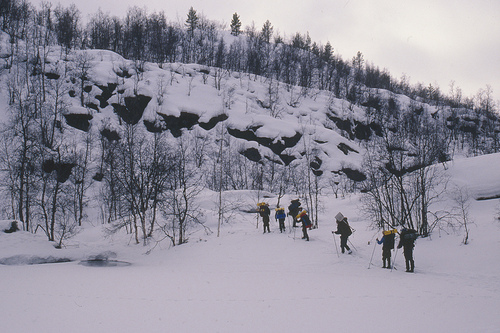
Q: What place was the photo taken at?
A: It was taken at the place.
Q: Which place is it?
A: It is a place.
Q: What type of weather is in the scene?
A: It is cloudy.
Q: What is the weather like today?
A: It is cloudy.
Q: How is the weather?
A: It is cloudy.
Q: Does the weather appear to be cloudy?
A: Yes, it is cloudy.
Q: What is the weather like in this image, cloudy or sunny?
A: It is cloudy.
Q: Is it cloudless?
A: No, it is cloudy.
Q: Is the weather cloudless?
A: No, it is cloudy.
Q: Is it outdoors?
A: Yes, it is outdoors.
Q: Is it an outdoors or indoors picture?
A: It is outdoors.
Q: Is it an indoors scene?
A: No, it is outdoors.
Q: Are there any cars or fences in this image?
A: No, there are no fences or cars.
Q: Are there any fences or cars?
A: No, there are no fences or cars.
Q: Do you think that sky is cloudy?
A: Yes, the sky is cloudy.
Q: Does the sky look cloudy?
A: Yes, the sky is cloudy.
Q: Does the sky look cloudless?
A: No, the sky is cloudy.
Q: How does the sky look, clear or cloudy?
A: The sky is cloudy.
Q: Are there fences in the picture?
A: No, there are no fences.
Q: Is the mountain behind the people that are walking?
A: Yes, the mountain is behind the people.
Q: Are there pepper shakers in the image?
A: No, there are no pepper shakers.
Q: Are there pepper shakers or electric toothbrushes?
A: No, there are no pepper shakers or electric toothbrushes.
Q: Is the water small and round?
A: Yes, the water is small and round.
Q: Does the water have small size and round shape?
A: Yes, the water is small and round.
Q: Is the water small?
A: Yes, the water is small.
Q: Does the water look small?
A: Yes, the water is small.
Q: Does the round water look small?
A: Yes, the water is small.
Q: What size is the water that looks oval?
A: The water is small.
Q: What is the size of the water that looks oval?
A: The water is small.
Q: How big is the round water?
A: The water is small.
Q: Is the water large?
A: No, the water is small.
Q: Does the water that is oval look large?
A: No, the water is small.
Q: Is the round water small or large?
A: The water is small.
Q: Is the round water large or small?
A: The water is small.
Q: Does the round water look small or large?
A: The water is small.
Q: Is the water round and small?
A: Yes, the water is round and small.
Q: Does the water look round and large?
A: No, the water is round but small.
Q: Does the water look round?
A: Yes, the water is round.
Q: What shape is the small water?
A: The water is round.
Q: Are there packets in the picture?
A: No, there are no packets.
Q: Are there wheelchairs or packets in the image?
A: No, there are no packets or wheelchairs.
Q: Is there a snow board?
A: No, there are no snowboards.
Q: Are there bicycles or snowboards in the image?
A: No, there are no snowboards or bicycles.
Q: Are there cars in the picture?
A: No, there are no cars.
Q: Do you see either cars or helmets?
A: No, there are no cars or helmets.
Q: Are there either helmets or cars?
A: No, there are no cars or helmets.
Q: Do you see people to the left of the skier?
A: Yes, there is a person to the left of the skier.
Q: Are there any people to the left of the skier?
A: Yes, there is a person to the left of the skier.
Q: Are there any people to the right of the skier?
A: No, the person is to the left of the skier.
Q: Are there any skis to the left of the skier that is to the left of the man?
A: No, there is a person to the left of the skier.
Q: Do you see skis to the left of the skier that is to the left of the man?
A: No, there is a person to the left of the skier.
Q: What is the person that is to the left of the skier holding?
A: The person is holding the stick.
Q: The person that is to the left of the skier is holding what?
A: The person is holding the stick.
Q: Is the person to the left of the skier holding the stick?
A: Yes, the person is holding the stick.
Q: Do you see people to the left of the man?
A: Yes, there is a person to the left of the man.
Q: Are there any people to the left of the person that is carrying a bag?
A: Yes, there is a person to the left of the man.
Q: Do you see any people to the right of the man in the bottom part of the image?
A: No, the person is to the left of the man.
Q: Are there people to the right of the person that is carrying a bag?
A: No, the person is to the left of the man.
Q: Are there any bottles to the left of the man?
A: No, there is a person to the left of the man.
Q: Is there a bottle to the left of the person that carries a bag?
A: No, there is a person to the left of the man.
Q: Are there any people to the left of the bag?
A: Yes, there is a person to the left of the bag.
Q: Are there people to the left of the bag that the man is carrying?
A: Yes, there is a person to the left of the bag.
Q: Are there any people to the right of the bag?
A: No, the person is to the left of the bag.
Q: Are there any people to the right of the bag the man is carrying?
A: No, the person is to the left of the bag.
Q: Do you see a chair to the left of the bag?
A: No, there is a person to the left of the bag.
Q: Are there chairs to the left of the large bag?
A: No, there is a person to the left of the bag.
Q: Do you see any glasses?
A: No, there are no glasses.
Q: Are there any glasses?
A: No, there are no glasses.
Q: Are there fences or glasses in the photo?
A: No, there are no glasses or fences.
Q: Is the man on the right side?
A: Yes, the man is on the right of the image.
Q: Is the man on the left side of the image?
A: No, the man is on the right of the image.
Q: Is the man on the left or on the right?
A: The man is on the right of the image.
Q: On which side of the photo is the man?
A: The man is on the right of the image.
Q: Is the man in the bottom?
A: Yes, the man is in the bottom of the image.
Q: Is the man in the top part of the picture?
A: No, the man is in the bottom of the image.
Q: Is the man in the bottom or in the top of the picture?
A: The man is in the bottom of the image.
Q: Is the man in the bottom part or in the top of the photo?
A: The man is in the bottom of the image.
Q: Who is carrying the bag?
A: The man is carrying the bag.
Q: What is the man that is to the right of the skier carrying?
A: The man is carrying a bag.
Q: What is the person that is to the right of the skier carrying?
A: The man is carrying a bag.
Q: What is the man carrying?
A: The man is carrying a bag.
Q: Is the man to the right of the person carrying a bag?
A: Yes, the man is carrying a bag.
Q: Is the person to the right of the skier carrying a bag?
A: Yes, the man is carrying a bag.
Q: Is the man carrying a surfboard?
A: No, the man is carrying a bag.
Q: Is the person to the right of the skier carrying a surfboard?
A: No, the man is carrying a bag.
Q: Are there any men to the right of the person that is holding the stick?
A: Yes, there is a man to the right of the person.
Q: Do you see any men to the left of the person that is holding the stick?
A: No, the man is to the right of the person.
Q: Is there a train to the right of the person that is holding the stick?
A: No, there is a man to the right of the person.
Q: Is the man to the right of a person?
A: Yes, the man is to the right of a person.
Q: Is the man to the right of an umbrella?
A: No, the man is to the right of a person.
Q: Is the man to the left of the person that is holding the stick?
A: No, the man is to the right of the person.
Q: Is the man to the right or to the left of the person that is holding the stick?
A: The man is to the right of the person.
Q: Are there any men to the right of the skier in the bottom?
A: Yes, there is a man to the right of the skier.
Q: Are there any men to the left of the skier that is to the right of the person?
A: No, the man is to the right of the skier.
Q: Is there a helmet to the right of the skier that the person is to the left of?
A: No, there is a man to the right of the skier.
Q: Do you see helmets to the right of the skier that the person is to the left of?
A: No, there is a man to the right of the skier.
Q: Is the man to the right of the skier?
A: Yes, the man is to the right of the skier.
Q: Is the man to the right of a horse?
A: No, the man is to the right of the skier.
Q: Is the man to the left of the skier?
A: No, the man is to the right of the skier.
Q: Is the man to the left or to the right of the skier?
A: The man is to the right of the skier.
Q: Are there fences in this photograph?
A: No, there are no fences.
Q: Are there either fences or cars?
A: No, there are no fences or cars.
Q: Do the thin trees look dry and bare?
A: Yes, the trees are dry and bare.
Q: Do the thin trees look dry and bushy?
A: No, the trees are dry but bare.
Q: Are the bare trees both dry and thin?
A: Yes, the trees are dry and thin.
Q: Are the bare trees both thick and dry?
A: No, the trees are dry but thin.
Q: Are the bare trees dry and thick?
A: No, the trees are dry but thin.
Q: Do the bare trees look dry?
A: Yes, the trees are dry.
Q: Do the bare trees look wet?
A: No, the trees are dry.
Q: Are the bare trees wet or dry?
A: The trees are dry.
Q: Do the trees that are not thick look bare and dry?
A: Yes, the trees are bare and dry.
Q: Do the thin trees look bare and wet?
A: No, the trees are bare but dry.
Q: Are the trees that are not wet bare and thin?
A: Yes, the trees are bare and thin.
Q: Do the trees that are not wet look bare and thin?
A: Yes, the trees are bare and thin.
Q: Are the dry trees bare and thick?
A: No, the trees are bare but thin.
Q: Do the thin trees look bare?
A: Yes, the trees are bare.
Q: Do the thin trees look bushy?
A: No, the trees are bare.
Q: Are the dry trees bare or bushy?
A: The trees are bare.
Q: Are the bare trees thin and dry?
A: Yes, the trees are thin and dry.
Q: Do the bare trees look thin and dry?
A: Yes, the trees are thin and dry.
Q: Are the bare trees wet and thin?
A: No, the trees are thin but dry.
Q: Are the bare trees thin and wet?
A: No, the trees are thin but dry.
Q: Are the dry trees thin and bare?
A: Yes, the trees are thin and bare.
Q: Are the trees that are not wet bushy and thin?
A: No, the trees are thin but bare.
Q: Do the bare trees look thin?
A: Yes, the trees are thin.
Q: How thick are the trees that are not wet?
A: The trees are thin.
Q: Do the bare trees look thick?
A: No, the trees are thin.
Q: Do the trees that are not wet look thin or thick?
A: The trees are thin.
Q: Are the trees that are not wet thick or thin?
A: The trees are thin.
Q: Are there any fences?
A: No, there are no fences.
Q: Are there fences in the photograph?
A: No, there are no fences.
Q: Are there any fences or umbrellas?
A: No, there are no fences or umbrellas.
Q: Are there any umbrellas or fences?
A: No, there are no fences or umbrellas.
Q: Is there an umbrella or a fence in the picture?
A: No, there are no fences or umbrellas.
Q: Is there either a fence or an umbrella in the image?
A: No, there are no fences or umbrellas.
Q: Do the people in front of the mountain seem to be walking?
A: Yes, the people are walking.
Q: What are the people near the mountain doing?
A: The people are walking.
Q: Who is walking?
A: The people are walking.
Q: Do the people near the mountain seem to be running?
A: No, the people are walking.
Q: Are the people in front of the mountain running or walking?
A: The people are walking.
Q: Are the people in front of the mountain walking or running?
A: The people are walking.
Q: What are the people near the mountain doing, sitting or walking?
A: The people are walking.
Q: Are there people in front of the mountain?
A: Yes, there are people in front of the mountain.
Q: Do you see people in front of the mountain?
A: Yes, there are people in front of the mountain.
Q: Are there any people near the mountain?
A: Yes, there are people near the mountain.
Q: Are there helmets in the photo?
A: No, there are no helmets.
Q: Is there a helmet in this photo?
A: No, there are no helmets.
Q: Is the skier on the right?
A: Yes, the skier is on the right of the image.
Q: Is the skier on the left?
A: No, the skier is on the right of the image.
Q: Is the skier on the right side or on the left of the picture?
A: The skier is on the right of the image.